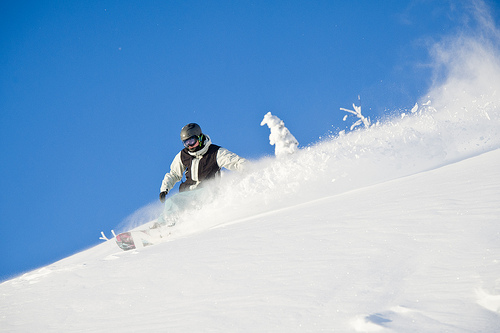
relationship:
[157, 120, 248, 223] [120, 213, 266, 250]
person riding snowboard